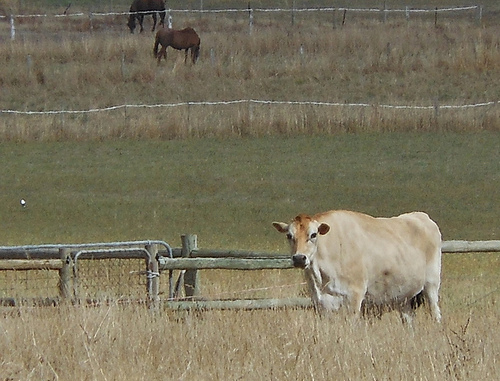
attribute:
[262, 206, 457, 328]
white cow — large, tan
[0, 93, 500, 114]
rope — long, white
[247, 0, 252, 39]
pole — small, white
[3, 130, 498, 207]
green grass — short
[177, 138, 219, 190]
grass — short, green, yellow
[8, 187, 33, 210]
bird — little, white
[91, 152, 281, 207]
grass — short, green, yellow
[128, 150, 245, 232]
grass — short, green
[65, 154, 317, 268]
grass — short, green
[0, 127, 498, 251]
grass — short, green, yellow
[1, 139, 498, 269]
grass — short, green, yellow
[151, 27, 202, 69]
brown horse — dark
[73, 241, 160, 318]
gate — metal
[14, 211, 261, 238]
grass — yellow, short, green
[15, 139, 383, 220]
grass — short, green, yellow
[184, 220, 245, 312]
fence — wooden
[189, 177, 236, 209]
short grass — green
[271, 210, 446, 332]
cow — standing, large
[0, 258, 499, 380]
grass — tall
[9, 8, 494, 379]
grass — short, green, dark brown, tall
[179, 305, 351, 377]
grass — tall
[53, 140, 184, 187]
grass — yellow, green, short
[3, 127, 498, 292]
grass — short, green, yellow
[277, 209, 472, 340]
cow — standing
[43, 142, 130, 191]
grass — short, green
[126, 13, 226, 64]
horse — small, brown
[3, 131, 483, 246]
grass — short, green, yellow